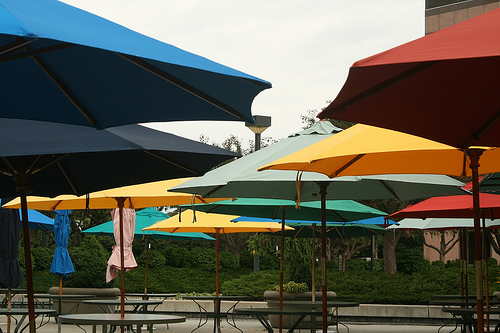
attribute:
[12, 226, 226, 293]
bushes — neatly trimmed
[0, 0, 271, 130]
umbrella — open, blue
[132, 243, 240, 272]
bushes — green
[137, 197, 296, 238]
umbrella — open, yellow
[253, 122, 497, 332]
umbrella — open, yellow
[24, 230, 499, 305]
bushes — green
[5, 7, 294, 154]
umbrella — open, blue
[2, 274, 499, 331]
tables — green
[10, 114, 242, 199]
umbrella — open, yellow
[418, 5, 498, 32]
building — tan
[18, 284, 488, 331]
tables — round 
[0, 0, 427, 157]
cloudy — white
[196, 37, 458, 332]
umbrellas — closed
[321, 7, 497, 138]
umbrella — open, red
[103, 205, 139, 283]
umbrella — closed, pink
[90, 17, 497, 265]
umbrellas — bunched 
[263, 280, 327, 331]
pot — concrete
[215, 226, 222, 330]
pole — wooden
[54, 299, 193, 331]
table — round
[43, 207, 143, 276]
umbrellas — closed, patio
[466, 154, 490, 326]
pole — yellow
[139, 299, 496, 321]
wall — cement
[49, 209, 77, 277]
umbrella — blue, closed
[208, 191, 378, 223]
umbrella — open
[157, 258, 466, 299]
wall — patio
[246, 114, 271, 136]
light — black 